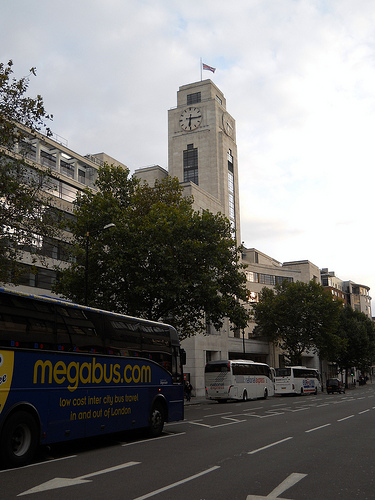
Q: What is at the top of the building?
A: A flag.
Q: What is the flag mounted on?
A: A pole.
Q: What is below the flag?
A: A clock.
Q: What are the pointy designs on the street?
A: Arrows.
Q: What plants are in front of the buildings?
A: Trees.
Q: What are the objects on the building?
A: Windows.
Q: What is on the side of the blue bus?
A: Yellow letters.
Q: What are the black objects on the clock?
A: Hands.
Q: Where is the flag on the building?
A: The roof.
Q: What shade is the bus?
A: Blue and yellow.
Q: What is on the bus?
A: Blue and yellow letters.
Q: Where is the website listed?
A: Blue bus.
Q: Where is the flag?
A: Clock tower.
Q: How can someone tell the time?
A: Clock.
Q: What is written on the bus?
A: Megabus.com.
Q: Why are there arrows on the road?
A: To show direction.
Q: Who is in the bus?
A: The driver.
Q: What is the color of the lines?
A: White.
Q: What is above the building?
A: A flag.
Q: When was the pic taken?
A: During the day.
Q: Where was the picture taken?
A: In the street.